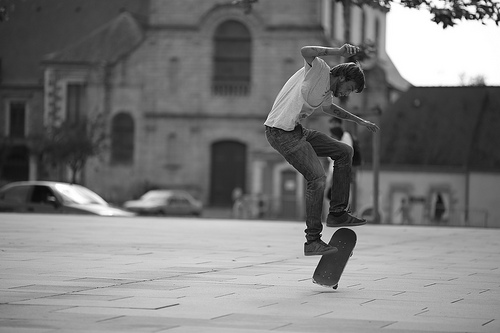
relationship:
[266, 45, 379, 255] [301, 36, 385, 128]
man has arms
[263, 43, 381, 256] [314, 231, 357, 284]
man on skateboard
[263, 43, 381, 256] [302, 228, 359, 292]
man riding skateboard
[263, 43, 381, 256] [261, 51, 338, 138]
man wearing shirt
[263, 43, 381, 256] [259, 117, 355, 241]
man wearing jeans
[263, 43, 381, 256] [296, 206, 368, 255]
man wearing dark shoes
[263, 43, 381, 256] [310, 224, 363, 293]
man above skateboard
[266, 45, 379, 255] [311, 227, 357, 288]
man above skateboard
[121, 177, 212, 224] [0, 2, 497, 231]
car near building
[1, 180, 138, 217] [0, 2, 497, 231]
car across from building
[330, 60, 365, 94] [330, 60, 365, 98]
hair on head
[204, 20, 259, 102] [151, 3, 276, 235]
window on building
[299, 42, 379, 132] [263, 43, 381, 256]
arms are on man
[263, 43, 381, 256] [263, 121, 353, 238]
man wearing jeans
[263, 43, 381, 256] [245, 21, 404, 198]
man wearing shirt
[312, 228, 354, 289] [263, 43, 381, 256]
skateboard with man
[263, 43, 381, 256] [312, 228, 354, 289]
man on skateboard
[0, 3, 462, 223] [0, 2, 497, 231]
windows on building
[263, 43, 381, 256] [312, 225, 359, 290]
man riding skateboard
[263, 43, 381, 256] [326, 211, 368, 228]
man wearing tennis shoes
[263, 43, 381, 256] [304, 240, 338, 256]
man wearing dark shoes